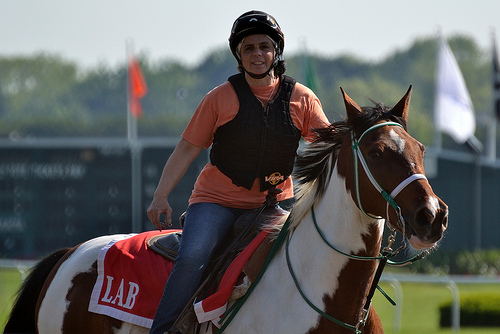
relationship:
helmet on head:
[229, 10, 284, 55] [230, 31, 281, 81]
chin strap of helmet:
[241, 64, 273, 83] [225, 6, 286, 50]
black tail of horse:
[6, 230, 93, 327] [3, 85, 447, 331]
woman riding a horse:
[148, 10, 344, 332] [3, 85, 447, 331]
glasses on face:
[240, 39, 272, 54] [233, 32, 274, 73]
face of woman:
[233, 32, 274, 73] [148, 10, 344, 332]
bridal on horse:
[268, 85, 465, 315] [3, 85, 447, 331]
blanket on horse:
[84, 221, 277, 326] [3, 85, 447, 331]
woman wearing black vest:
[148, 10, 344, 332] [210, 73, 299, 191]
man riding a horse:
[143, 10, 380, 334] [3, 85, 447, 331]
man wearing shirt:
[143, 6, 352, 323] [180, 68, 328, 213]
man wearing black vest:
[143, 10, 380, 334] [210, 75, 299, 191]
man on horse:
[143, 10, 380, 334] [50, 201, 467, 312]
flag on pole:
[127, 54, 147, 121] [123, 50, 147, 232]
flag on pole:
[437, 42, 482, 145] [436, 21, 439, 241]